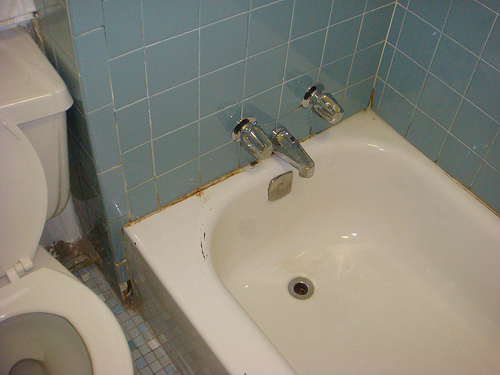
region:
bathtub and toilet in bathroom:
[20, 26, 405, 339]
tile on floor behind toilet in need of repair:
[47, 227, 109, 297]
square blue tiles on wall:
[108, 35, 210, 160]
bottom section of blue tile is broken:
[111, 228, 148, 313]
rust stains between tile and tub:
[129, 170, 244, 218]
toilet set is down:
[0, 262, 138, 373]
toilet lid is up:
[9, 100, 66, 280]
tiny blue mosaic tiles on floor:
[134, 329, 171, 369]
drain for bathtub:
[282, 261, 323, 303]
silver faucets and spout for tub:
[228, 92, 358, 182]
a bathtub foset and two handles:
[229, 83, 339, 181]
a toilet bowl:
[4, 26, 117, 374]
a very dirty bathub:
[107, 72, 424, 239]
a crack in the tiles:
[112, 230, 144, 313]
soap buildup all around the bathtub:
[130, 89, 397, 238]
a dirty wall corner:
[32, 220, 128, 277]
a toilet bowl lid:
[0, 104, 86, 289]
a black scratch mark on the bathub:
[186, 208, 230, 287]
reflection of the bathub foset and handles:
[187, 38, 329, 129]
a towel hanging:
[0, 6, 42, 41]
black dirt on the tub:
[196, 234, 208, 264]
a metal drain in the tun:
[283, 274, 323, 299]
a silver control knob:
[241, 125, 273, 160]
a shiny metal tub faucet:
[279, 134, 316, 173]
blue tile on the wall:
[149, 17, 226, 122]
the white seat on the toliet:
[46, 280, 101, 314]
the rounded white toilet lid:
[2, 147, 44, 235]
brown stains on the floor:
[120, 286, 133, 307]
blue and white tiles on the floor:
[136, 327, 156, 368]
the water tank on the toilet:
[17, 46, 54, 103]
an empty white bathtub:
[115, 104, 498, 374]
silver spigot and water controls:
[204, 80, 361, 182]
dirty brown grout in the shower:
[130, 170, 253, 222]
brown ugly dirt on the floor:
[51, 234, 103, 274]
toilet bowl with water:
[1, 314, 110, 374]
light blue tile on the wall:
[110, 57, 214, 176]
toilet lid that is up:
[2, 114, 54, 289]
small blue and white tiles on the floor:
[131, 326, 167, 373]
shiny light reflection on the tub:
[308, 222, 378, 270]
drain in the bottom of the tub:
[287, 274, 319, 306]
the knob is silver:
[287, 72, 353, 139]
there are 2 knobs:
[210, 61, 375, 158]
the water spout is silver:
[270, 117, 316, 189]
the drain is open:
[272, 262, 332, 307]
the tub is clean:
[159, 140, 498, 365]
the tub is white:
[165, 109, 498, 363]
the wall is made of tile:
[124, 8, 360, 125]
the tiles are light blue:
[144, 6, 351, 112]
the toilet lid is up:
[0, 134, 127, 374]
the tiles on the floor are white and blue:
[121, 310, 167, 368]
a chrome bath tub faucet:
[270, 127, 315, 178]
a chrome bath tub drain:
[287, 277, 312, 299]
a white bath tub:
[121, 106, 498, 373]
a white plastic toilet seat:
[1, 267, 131, 373]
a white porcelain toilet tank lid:
[2, 27, 71, 128]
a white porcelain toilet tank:
[17, 112, 68, 219]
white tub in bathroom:
[119, 99, 498, 372]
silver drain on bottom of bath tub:
[283, 269, 318, 303]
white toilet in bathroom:
[0, 20, 140, 372]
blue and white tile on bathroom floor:
[72, 260, 182, 374]